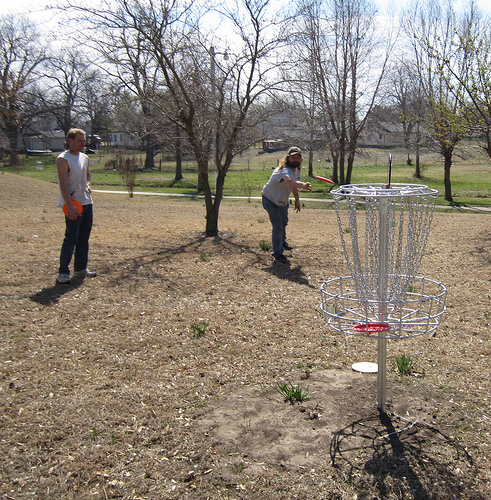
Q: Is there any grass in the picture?
A: Yes, there is grass.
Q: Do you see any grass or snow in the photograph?
A: Yes, there is grass.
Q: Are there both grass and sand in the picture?
A: No, there is grass but no sand.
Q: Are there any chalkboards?
A: No, there are no chalkboards.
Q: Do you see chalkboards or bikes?
A: No, there are no chalkboards or bikes.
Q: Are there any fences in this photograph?
A: No, there are no fences.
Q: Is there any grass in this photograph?
A: Yes, there is grass.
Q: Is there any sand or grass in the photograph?
A: Yes, there is grass.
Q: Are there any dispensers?
A: No, there are no dispensers.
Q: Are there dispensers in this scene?
A: No, there are no dispensers.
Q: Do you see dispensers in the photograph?
A: No, there are no dispensers.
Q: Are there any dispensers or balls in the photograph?
A: No, there are no dispensers or balls.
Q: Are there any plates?
A: No, there are no plates.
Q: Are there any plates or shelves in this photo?
A: No, there are no plates or shelves.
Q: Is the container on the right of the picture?
A: Yes, the container is on the right of the image.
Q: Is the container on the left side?
A: No, the container is on the right of the image.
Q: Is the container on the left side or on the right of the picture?
A: The container is on the right of the image.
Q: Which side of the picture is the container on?
A: The container is on the right of the image.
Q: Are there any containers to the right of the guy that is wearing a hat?
A: Yes, there is a container to the right of the guy.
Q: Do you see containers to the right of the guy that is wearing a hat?
A: Yes, there is a container to the right of the guy.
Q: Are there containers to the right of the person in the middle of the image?
A: Yes, there is a container to the right of the guy.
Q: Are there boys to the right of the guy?
A: No, there is a container to the right of the guy.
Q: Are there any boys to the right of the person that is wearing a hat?
A: No, there is a container to the right of the guy.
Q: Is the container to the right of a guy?
A: Yes, the container is to the right of a guy.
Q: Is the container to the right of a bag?
A: No, the container is to the right of a guy.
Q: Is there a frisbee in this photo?
A: Yes, there is a frisbee.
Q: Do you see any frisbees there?
A: Yes, there is a frisbee.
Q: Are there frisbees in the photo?
A: Yes, there is a frisbee.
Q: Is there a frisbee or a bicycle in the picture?
A: Yes, there is a frisbee.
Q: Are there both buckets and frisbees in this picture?
A: No, there is a frisbee but no buckets.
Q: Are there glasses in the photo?
A: No, there are no glasses.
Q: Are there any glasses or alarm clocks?
A: No, there are no glasses or alarm clocks.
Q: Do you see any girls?
A: No, there are no girls.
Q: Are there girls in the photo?
A: No, there are no girls.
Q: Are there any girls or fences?
A: No, there are no girls or fences.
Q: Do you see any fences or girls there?
A: No, there are no girls or fences.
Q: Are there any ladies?
A: No, there are no ladies.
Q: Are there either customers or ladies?
A: No, there are no ladies or customers.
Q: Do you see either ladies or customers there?
A: No, there are no ladies or customers.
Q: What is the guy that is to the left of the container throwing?
A: The guy is throwing the frisbee.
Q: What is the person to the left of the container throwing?
A: The guy is throwing the frisbee.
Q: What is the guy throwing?
A: The guy is throwing the frisbee.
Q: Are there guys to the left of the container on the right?
A: Yes, there is a guy to the left of the container.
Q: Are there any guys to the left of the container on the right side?
A: Yes, there is a guy to the left of the container.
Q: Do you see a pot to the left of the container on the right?
A: No, there is a guy to the left of the container.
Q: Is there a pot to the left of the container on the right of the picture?
A: No, there is a guy to the left of the container.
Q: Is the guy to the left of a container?
A: Yes, the guy is to the left of a container.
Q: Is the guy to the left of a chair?
A: No, the guy is to the left of a container.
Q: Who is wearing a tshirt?
A: The guy is wearing a tshirt.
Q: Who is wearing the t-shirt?
A: The guy is wearing a tshirt.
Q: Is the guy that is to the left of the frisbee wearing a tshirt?
A: Yes, the guy is wearing a tshirt.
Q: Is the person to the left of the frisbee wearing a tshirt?
A: Yes, the guy is wearing a tshirt.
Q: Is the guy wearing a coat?
A: No, the guy is wearing a tshirt.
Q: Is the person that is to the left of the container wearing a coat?
A: No, the guy is wearing a tshirt.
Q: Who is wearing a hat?
A: The guy is wearing a hat.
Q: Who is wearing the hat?
A: The guy is wearing a hat.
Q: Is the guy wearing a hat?
A: Yes, the guy is wearing a hat.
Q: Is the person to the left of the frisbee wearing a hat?
A: Yes, the guy is wearing a hat.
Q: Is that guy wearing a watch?
A: No, the guy is wearing a hat.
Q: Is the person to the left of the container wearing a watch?
A: No, the guy is wearing a hat.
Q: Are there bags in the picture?
A: No, there are no bags.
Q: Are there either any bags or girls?
A: No, there are no bags or girls.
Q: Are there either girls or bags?
A: No, there are no bags or girls.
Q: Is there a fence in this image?
A: No, there are no fences.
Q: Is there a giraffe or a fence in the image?
A: No, there are no fences or giraffes.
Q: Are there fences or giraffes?
A: No, there are no fences or giraffes.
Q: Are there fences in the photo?
A: No, there are no fences.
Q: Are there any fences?
A: No, there are no fences.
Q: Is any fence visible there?
A: No, there are no fences.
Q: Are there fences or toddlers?
A: No, there are no fences or toddlers.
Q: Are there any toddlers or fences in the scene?
A: No, there are no fences or toddlers.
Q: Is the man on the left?
A: Yes, the man is on the left of the image.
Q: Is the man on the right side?
A: No, the man is on the left of the image.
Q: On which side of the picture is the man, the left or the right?
A: The man is on the left of the image.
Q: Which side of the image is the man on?
A: The man is on the left of the image.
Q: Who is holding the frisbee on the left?
A: The man is holding the frisbee.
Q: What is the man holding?
A: The man is holding the frisbee.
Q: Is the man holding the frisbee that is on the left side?
A: Yes, the man is holding the frisbee.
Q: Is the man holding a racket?
A: No, the man is holding the frisbee.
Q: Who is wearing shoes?
A: The man is wearing shoes.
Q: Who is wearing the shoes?
A: The man is wearing shoes.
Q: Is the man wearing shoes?
A: Yes, the man is wearing shoes.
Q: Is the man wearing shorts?
A: No, the man is wearing shoes.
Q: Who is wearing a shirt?
A: The man is wearing a shirt.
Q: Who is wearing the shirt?
A: The man is wearing a shirt.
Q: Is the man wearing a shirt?
A: Yes, the man is wearing a shirt.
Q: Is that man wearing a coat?
A: No, the man is wearing a shirt.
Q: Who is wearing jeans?
A: The man is wearing jeans.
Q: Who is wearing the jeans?
A: The man is wearing jeans.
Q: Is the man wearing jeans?
A: Yes, the man is wearing jeans.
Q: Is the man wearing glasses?
A: No, the man is wearing jeans.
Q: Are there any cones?
A: No, there are no cones.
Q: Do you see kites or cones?
A: No, there are no cones or kites.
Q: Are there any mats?
A: No, there are no mats.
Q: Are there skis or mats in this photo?
A: No, there are no mats or skis.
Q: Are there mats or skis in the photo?
A: No, there are no mats or skis.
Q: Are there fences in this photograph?
A: No, there are no fences.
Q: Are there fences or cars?
A: No, there are no fences or cars.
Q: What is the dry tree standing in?
A: The tree is standing in the grass.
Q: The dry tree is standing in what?
A: The tree is standing in the grass.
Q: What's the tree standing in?
A: The tree is standing in the grass.